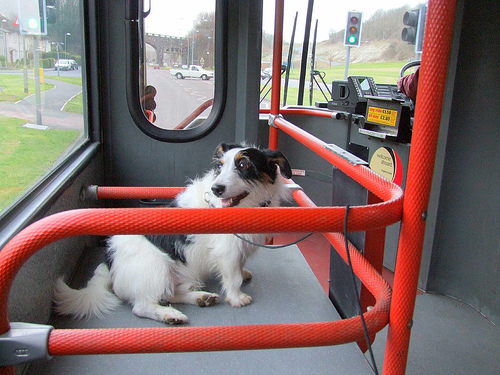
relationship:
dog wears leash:
[51, 137, 303, 321] [203, 196, 379, 374]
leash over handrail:
[203, 196, 379, 374] [3, 114, 404, 359]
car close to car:
[53, 57, 71, 70] [53, 57, 71, 70]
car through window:
[53, 57, 71, 70] [0, 0, 97, 219]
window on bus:
[0, 0, 97, 219] [4, 4, 499, 373]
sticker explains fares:
[368, 105, 403, 127] [378, 107, 393, 123]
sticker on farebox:
[368, 105, 403, 127] [330, 72, 409, 141]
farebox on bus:
[330, 72, 409, 141] [4, 4, 499, 373]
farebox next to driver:
[330, 72, 409, 141] [396, 59, 420, 105]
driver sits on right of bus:
[396, 59, 420, 105] [288, 0, 497, 298]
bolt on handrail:
[406, 317, 417, 333] [3, 114, 404, 359]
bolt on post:
[420, 209, 430, 224] [387, 1, 465, 374]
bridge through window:
[145, 32, 208, 69] [136, 1, 226, 139]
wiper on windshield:
[283, 9, 300, 107] [262, 1, 426, 116]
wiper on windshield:
[307, 17, 321, 107] [262, 1, 426, 116]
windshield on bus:
[262, 1, 426, 116] [4, 4, 499, 373]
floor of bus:
[269, 210, 426, 323] [4, 4, 499, 373]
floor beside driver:
[269, 210, 426, 323] [396, 59, 420, 105]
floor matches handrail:
[269, 210, 426, 323] [3, 114, 404, 359]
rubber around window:
[123, 3, 233, 142] [136, 1, 226, 139]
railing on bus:
[173, 100, 216, 132] [4, 4, 499, 373]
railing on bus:
[258, 104, 332, 120] [4, 4, 499, 373]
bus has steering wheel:
[4, 4, 499, 373] [399, 57, 421, 88]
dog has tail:
[51, 137, 303, 321] [49, 256, 126, 320]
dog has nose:
[51, 137, 303, 321] [210, 183, 228, 198]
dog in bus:
[51, 137, 303, 321] [4, 4, 499, 373]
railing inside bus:
[258, 104, 332, 120] [4, 4, 499, 373]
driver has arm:
[396, 59, 420, 105] [397, 66, 419, 104]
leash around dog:
[203, 196, 379, 374] [51, 137, 303, 321]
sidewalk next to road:
[11, 66, 90, 132] [141, 59, 282, 135]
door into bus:
[100, 2, 262, 207] [4, 4, 499, 373]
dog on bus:
[51, 137, 303, 321] [4, 4, 499, 373]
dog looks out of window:
[51, 137, 303, 321] [0, 0, 97, 219]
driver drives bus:
[396, 59, 420, 105] [4, 4, 499, 373]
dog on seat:
[51, 137, 303, 321] [33, 183, 378, 374]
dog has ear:
[51, 137, 303, 321] [262, 147, 294, 181]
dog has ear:
[51, 137, 303, 321] [212, 140, 242, 156]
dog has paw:
[51, 137, 303, 321] [227, 290, 257, 313]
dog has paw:
[51, 137, 303, 321] [161, 307, 190, 326]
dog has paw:
[51, 137, 303, 321] [239, 268, 258, 281]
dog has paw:
[51, 137, 303, 321] [195, 291, 224, 310]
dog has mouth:
[51, 137, 303, 321] [219, 193, 252, 208]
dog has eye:
[51, 137, 303, 321] [238, 161, 247, 169]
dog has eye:
[51, 137, 303, 321] [218, 161, 224, 170]